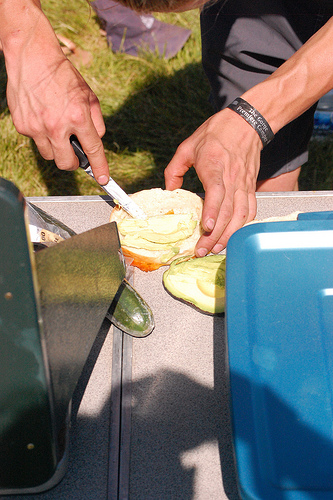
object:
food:
[104, 188, 205, 274]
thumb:
[163, 142, 191, 189]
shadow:
[0, 367, 221, 500]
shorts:
[196, 0, 333, 176]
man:
[0, 0, 333, 259]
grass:
[0, 0, 332, 196]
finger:
[196, 167, 226, 232]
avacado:
[162, 254, 227, 316]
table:
[1, 190, 333, 498]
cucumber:
[105, 279, 156, 338]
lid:
[0, 177, 59, 497]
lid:
[226, 210, 333, 500]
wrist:
[0, 0, 48, 60]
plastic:
[105, 280, 157, 339]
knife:
[69, 133, 147, 220]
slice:
[118, 212, 194, 246]